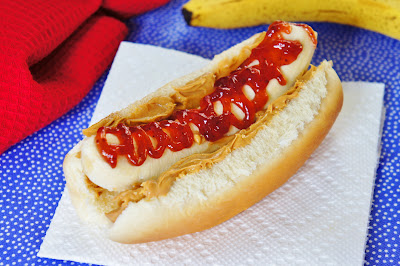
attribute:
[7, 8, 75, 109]
towel — red 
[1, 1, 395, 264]
stars — white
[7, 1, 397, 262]
tablecloth — White , Blue 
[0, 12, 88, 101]
towel — red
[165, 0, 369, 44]
banana — white 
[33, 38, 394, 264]
napkin — white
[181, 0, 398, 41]
banana — yellow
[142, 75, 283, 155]
jelly — red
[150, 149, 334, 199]
bun — brown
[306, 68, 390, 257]
napkin — white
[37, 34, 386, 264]
towel — paper towel, folded, paper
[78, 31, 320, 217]
peanut butter — Brown 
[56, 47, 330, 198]
banana — yellow 